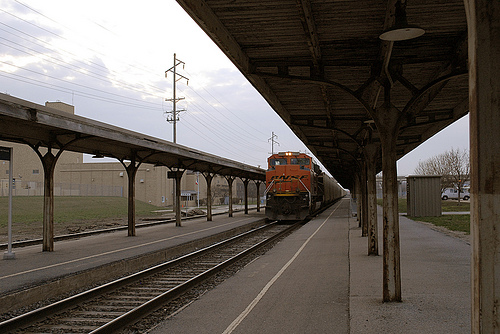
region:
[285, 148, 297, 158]
The lights on the top of the train.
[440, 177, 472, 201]
The white car parked in the parking lot.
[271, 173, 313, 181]
The black letters on the train.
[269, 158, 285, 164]
The left window of the train.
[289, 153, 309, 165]
The right window of the train.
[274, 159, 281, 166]
The white paper in the left window of the train.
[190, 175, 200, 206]
The blue, white and red flag on the pole.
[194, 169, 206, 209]
The pole the flag is flying from.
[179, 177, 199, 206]
The small tan building next to the flag pole.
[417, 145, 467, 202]
The tree next to the parking lot on the right.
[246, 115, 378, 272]
Train on the tracks.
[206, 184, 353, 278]
Tracks under the train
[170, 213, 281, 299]
Gravel on the tracks.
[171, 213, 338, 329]
Steel rails on the track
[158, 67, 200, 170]
Power line behind the tracks.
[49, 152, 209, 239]
Grass by the tracks.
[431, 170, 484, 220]
Vehicle in the background.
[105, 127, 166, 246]
Pole on the bridge.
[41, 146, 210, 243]
Building in the background.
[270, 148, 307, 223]
Windows on the train.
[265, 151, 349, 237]
This is a train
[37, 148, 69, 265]
This is a pillar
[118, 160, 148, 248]
This is a pillar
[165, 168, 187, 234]
This is a pillar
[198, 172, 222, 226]
This is a pillar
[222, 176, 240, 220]
This is a pillar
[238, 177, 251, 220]
This is a pillar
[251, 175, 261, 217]
This is a pillar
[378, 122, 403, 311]
This is a pillar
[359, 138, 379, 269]
This is a pillar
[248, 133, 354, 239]
A train on the tracks.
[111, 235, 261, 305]
Gravel in between and on the side of the train.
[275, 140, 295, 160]
The top of the train has lights.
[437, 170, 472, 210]
A white car parked.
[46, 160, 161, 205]
A fence around the building.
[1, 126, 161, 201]
A building on the side of the tracks.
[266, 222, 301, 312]
A white line on the sidewalk.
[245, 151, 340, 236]
The train is orange.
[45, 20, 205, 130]
The blue sky is cloudy.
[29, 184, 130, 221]
The grass is green.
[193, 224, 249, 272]
Train tracks in front of the train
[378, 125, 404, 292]
A pillar holding up the station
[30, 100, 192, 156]
The roof of the station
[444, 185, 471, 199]
A white van in the distance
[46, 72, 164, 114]
Wires connected to the tellphone pole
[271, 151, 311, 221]
The front of the train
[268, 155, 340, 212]
A train on the tracks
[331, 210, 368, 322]
A platform by the train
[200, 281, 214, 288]
Gravel near the train tracks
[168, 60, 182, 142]
A telephone by the station